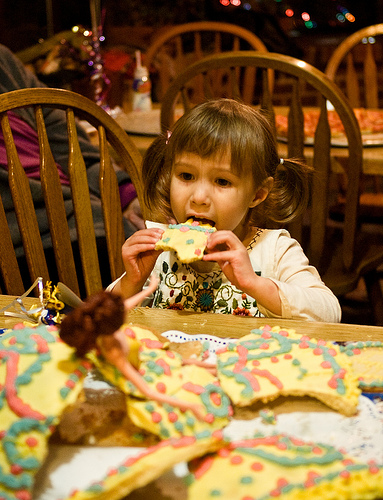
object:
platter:
[306, 132, 383, 148]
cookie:
[214, 324, 362, 417]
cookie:
[210, 317, 363, 417]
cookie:
[0, 219, 380, 498]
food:
[154, 218, 215, 262]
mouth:
[185, 212, 216, 228]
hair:
[138, 98, 313, 223]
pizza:
[269, 108, 383, 138]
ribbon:
[0, 277, 65, 326]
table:
[0, 295, 383, 500]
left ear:
[248, 176, 273, 208]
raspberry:
[146, 220, 167, 235]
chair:
[0, 85, 158, 309]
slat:
[0, 85, 143, 299]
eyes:
[179, 171, 195, 180]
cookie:
[338, 340, 381, 397]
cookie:
[53, 430, 225, 500]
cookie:
[0, 318, 95, 500]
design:
[153, 248, 269, 318]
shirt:
[104, 220, 342, 324]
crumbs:
[201, 320, 207, 326]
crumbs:
[183, 321, 188, 326]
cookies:
[186, 434, 383, 500]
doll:
[59, 271, 207, 422]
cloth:
[0, 292, 383, 500]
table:
[74, 105, 380, 177]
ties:
[280, 158, 284, 165]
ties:
[166, 130, 173, 145]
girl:
[105, 100, 341, 328]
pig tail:
[256, 159, 319, 223]